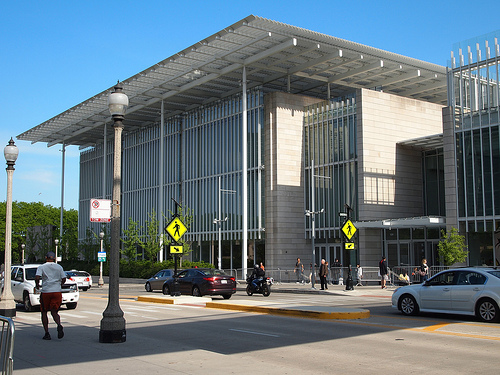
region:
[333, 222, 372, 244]
a cross walk sign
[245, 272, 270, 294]
a motorcycle riding down road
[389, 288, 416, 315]
a black car tire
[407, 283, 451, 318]
a grey car on the road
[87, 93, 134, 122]
a light on a pole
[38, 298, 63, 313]
a man wearing red shorts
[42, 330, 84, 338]
a man walking a side of road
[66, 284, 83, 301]
a white cars headlights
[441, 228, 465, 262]
a tree next to a building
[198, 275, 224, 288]
a red cars tail light on the road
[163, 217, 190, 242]
a bright yellow pedestrian crossing sign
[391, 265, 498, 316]
a silver sedan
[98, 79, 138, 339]
a tall gray lamp post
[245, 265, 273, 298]
a man on a motorcycle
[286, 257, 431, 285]
a crowd of people waiting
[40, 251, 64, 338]
a man in red shorts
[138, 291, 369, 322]
a road divider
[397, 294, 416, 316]
a black front tire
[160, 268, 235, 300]
a red sedan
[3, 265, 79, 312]
a white truck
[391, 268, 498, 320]
A car on the street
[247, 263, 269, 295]
A motorcycle on the street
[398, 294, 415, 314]
The front tire of the car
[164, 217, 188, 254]
A yellow sign above the street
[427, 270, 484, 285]
Windows on the car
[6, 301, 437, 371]
A shadow on the road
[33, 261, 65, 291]
The man is wearing a white shirt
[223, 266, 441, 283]
A fence on the sidewalk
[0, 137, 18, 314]
A lamp post by the road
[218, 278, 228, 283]
A license plate behind the car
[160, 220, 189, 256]
pedestrian crossing sign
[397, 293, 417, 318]
front left wheel on a car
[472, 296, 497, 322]
rear left wheel on a car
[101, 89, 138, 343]
street lamp on a post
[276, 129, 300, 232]
stone exterior of a building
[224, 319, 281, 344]
white painted line on a street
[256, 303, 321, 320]
yellow painted curb on an island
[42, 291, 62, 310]
a person wearing red shorts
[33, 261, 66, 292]
a person wearing a white shirt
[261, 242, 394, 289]
a group of people in front of a building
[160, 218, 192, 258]
yellow pedestrian crossing sign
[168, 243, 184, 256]
arrow pointing to the right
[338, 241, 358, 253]
arrow pointing to the left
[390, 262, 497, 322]
white car driving down the road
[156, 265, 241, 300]
dark red car in the road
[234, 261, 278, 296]
person riding a motorcycle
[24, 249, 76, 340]
person jogging on the sidewalk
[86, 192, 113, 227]
red and white sign on a pole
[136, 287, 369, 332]
traffic island with a yellow curb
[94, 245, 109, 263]
green and white street sign